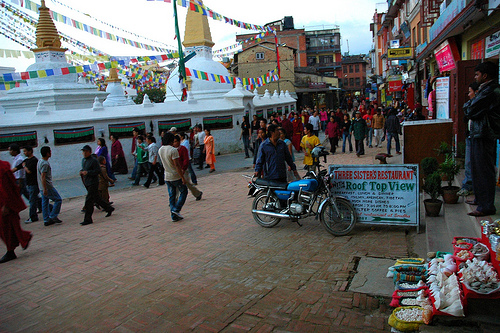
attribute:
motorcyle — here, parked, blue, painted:
[252, 157, 350, 221]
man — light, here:
[252, 127, 308, 175]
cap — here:
[72, 140, 98, 154]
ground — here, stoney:
[121, 234, 251, 310]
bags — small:
[388, 247, 458, 303]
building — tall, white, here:
[43, 13, 287, 128]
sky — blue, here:
[116, 1, 185, 58]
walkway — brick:
[269, 253, 331, 329]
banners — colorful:
[146, 45, 242, 94]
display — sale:
[345, 178, 433, 241]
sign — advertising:
[322, 166, 465, 280]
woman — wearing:
[205, 112, 218, 167]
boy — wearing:
[301, 112, 332, 173]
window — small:
[240, 39, 282, 68]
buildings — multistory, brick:
[220, 14, 303, 92]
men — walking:
[72, 138, 146, 189]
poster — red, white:
[359, 162, 413, 212]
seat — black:
[257, 166, 293, 194]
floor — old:
[334, 222, 414, 261]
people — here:
[112, 132, 180, 190]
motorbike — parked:
[280, 181, 351, 231]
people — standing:
[454, 61, 493, 200]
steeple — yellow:
[22, 7, 69, 72]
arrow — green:
[366, 208, 420, 227]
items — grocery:
[388, 246, 494, 307]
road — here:
[66, 221, 184, 286]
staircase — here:
[401, 222, 484, 243]